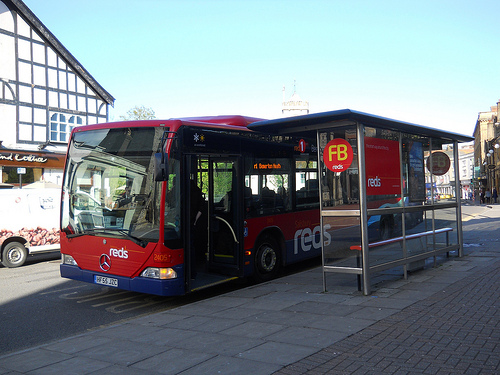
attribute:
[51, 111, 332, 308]
bus — red, blue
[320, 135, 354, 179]
sign — showing information, red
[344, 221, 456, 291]
seat — metal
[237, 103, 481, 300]
bus stop — clear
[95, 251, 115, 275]
symbol — existing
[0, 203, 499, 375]
sidewalk — cement, brick, existing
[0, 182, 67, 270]
vehicle — white, brown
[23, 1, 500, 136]
sky — existing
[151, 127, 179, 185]
mirror — existing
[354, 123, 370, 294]
edge — metal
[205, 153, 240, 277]
door — existing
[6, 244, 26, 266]
rim — existing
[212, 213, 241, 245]
handle — existing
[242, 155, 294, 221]
window — existing